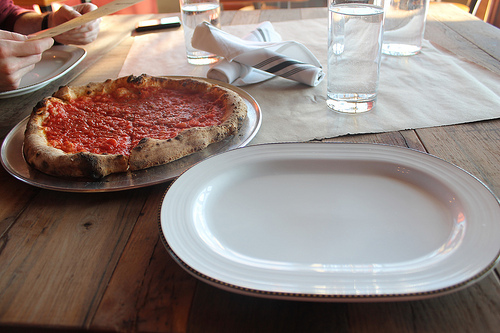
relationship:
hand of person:
[1, 28, 58, 92] [1, 0, 103, 95]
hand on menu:
[1, 28, 58, 92] [41, 3, 156, 40]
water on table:
[328, 7, 380, 110] [15, 21, 489, 322]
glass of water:
[181, 0, 216, 60] [328, 7, 380, 110]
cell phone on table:
[129, 14, 189, 39] [3, 1, 495, 326]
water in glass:
[388, 7, 417, 29] [377, 0, 427, 57]